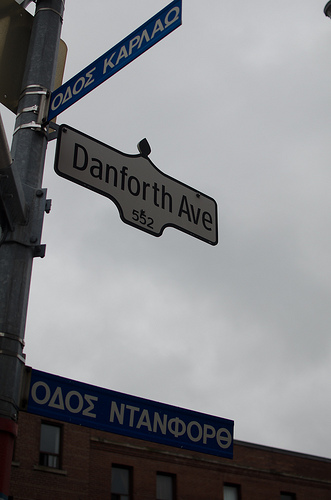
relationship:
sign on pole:
[53, 122, 218, 247] [4, 31, 62, 265]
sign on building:
[23, 358, 233, 458] [0, 404, 329, 497]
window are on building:
[40, 421, 63, 470] [0, 404, 329, 497]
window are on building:
[110, 463, 135, 499] [0, 404, 329, 497]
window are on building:
[155, 469, 177, 499] [0, 404, 329, 497]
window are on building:
[221, 480, 242, 499] [0, 404, 329, 497]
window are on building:
[278, 491, 297, 499] [0, 404, 329, 497]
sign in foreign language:
[23, 358, 233, 458] [28, 376, 231, 450]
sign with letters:
[53, 122, 218, 247] [71, 140, 213, 230]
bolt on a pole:
[43, 200, 50, 214] [5, 0, 68, 408]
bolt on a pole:
[34, 244, 44, 258] [5, 0, 68, 408]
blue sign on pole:
[47, 0, 196, 124] [12, 121, 45, 342]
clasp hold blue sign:
[11, 122, 40, 133] [45, 0, 182, 122]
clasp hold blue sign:
[14, 104, 39, 117] [45, 0, 182, 122]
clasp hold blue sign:
[22, 84, 48, 89] [45, 0, 182, 122]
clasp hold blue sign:
[24, 90, 47, 96] [45, 0, 182, 122]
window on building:
[110, 462, 136, 496] [1, 412, 330, 499]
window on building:
[40, 417, 63, 469] [1, 412, 330, 499]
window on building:
[155, 469, 177, 499] [1, 412, 330, 499]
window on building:
[221, 480, 242, 499] [1, 412, 330, 499]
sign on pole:
[53, 122, 218, 247] [0, 0, 64, 496]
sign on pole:
[23, 358, 233, 458] [0, 0, 64, 496]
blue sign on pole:
[45, 0, 182, 122] [0, 0, 64, 496]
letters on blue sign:
[50, 4, 180, 109] [45, 0, 182, 122]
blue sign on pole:
[45, 0, 182, 122] [0, 5, 73, 429]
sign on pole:
[44, 122, 240, 247] [0, 5, 73, 429]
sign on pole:
[23, 358, 233, 458] [18, 58, 38, 201]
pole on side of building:
[6, 75, 77, 403] [62, 436, 176, 499]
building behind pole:
[20, 451, 328, 498] [2, 219, 34, 486]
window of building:
[40, 421, 63, 470] [36, 433, 291, 496]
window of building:
[110, 463, 135, 499] [36, 433, 291, 496]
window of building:
[152, 465, 178, 498] [36, 433, 291, 496]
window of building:
[215, 477, 241, 498] [36, 433, 291, 496]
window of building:
[271, 483, 297, 497] [36, 433, 291, 496]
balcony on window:
[32, 415, 72, 475] [31, 421, 64, 472]